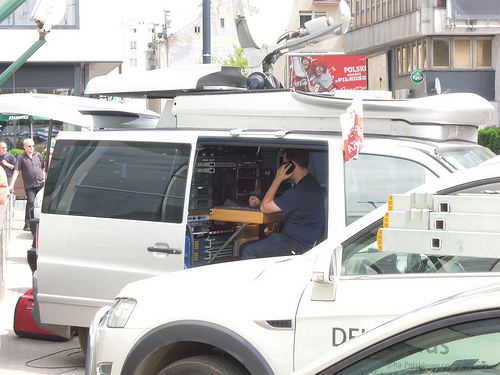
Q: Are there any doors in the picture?
A: Yes, there is a door.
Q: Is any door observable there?
A: Yes, there is a door.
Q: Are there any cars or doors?
A: Yes, there is a door.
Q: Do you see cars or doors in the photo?
A: Yes, there is a door.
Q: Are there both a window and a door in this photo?
A: Yes, there are both a door and a window.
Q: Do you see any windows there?
A: Yes, there is a window.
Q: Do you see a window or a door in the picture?
A: Yes, there is a window.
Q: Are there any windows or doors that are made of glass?
A: Yes, the window is made of glass.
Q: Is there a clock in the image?
A: No, there are no clocks.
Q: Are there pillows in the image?
A: No, there are no pillows.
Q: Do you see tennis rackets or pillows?
A: No, there are no pillows or tennis rackets.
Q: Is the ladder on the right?
A: Yes, the ladder is on the right of the image.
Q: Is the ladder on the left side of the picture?
A: No, the ladder is on the right of the image.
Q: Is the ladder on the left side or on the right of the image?
A: The ladder is on the right of the image.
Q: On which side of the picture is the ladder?
A: The ladder is on the right of the image.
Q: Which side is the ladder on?
A: The ladder is on the right of the image.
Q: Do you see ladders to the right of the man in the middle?
A: Yes, there is a ladder to the right of the man.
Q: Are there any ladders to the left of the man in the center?
A: No, the ladder is to the right of the man.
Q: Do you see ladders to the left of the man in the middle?
A: No, the ladder is to the right of the man.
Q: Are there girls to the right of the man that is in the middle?
A: No, there is a ladder to the right of the man.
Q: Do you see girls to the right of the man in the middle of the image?
A: No, there is a ladder to the right of the man.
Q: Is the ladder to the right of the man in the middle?
A: Yes, the ladder is to the right of the man.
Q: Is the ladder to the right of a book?
A: No, the ladder is to the right of the man.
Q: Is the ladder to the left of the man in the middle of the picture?
A: No, the ladder is to the right of the man.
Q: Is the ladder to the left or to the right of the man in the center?
A: The ladder is to the right of the man.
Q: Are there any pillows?
A: No, there are no pillows.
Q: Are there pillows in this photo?
A: No, there are no pillows.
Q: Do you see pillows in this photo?
A: No, there are no pillows.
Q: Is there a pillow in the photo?
A: No, there are no pillows.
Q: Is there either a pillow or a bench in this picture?
A: No, there are no pillows or benches.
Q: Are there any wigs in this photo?
A: No, there are no wigs.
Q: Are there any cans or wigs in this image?
A: No, there are no wigs or cans.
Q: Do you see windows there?
A: Yes, there is a window.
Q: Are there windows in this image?
A: Yes, there is a window.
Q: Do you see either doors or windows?
A: Yes, there is a window.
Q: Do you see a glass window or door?
A: Yes, there is a glass window.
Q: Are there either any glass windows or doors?
A: Yes, there is a glass window.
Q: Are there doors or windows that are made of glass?
A: Yes, the window is made of glass.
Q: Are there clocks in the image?
A: No, there are no clocks.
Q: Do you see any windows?
A: Yes, there is a window.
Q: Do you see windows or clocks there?
A: Yes, there is a window.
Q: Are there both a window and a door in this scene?
A: Yes, there are both a window and a door.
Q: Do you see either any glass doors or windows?
A: Yes, there is a glass window.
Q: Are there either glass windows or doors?
A: Yes, there is a glass window.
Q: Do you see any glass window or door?
A: Yes, there is a glass window.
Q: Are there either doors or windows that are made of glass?
A: Yes, the window is made of glass.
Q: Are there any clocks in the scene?
A: No, there are no clocks.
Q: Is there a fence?
A: No, there are no fences.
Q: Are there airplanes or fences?
A: No, there are no fences or airplanes.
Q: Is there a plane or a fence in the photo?
A: No, there are no fences or airplanes.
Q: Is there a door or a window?
A: Yes, there is a window.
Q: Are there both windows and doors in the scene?
A: Yes, there are both a window and a door.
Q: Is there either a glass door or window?
A: Yes, there is a glass window.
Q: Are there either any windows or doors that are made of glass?
A: Yes, the window is made of glass.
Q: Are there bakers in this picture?
A: No, there are no bakers.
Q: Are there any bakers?
A: No, there are no bakers.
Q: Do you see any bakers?
A: No, there are no bakers.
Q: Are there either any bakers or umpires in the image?
A: No, there are no bakers or umpires.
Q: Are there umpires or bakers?
A: No, there are no bakers or umpires.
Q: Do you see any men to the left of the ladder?
A: Yes, there is a man to the left of the ladder.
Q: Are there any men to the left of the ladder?
A: Yes, there is a man to the left of the ladder.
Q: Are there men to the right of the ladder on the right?
A: No, the man is to the left of the ladder.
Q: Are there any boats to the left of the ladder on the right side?
A: No, there is a man to the left of the ladder.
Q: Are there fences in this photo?
A: No, there are no fences.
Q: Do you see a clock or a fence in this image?
A: No, there are no fences or clocks.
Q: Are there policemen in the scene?
A: No, there are no policemen.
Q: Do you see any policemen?
A: No, there are no policemen.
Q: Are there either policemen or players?
A: No, there are no policemen or players.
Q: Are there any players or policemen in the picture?
A: No, there are no policemen or players.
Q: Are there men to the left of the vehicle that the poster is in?
A: Yes, there is a man to the left of the vehicle.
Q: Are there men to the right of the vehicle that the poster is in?
A: No, the man is to the left of the vehicle.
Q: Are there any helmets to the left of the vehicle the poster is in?
A: No, there is a man to the left of the vehicle.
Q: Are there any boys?
A: No, there are no boys.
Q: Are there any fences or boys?
A: No, there are no boys or fences.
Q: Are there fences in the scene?
A: No, there are no fences.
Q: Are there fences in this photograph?
A: No, there are no fences.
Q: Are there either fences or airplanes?
A: No, there are no fences or airplanes.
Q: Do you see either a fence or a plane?
A: No, there are no fences or airplanes.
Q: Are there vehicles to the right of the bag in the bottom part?
A: Yes, there is a vehicle to the right of the bag.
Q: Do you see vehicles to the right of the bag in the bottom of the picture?
A: Yes, there is a vehicle to the right of the bag.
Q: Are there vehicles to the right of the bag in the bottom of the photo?
A: Yes, there is a vehicle to the right of the bag.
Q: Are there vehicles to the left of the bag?
A: No, the vehicle is to the right of the bag.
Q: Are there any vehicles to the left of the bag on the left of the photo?
A: No, the vehicle is to the right of the bag.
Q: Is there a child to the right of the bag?
A: No, there is a vehicle to the right of the bag.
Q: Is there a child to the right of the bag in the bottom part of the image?
A: No, there is a vehicle to the right of the bag.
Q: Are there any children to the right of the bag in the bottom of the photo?
A: No, there is a vehicle to the right of the bag.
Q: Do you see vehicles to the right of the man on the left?
A: Yes, there is a vehicle to the right of the man.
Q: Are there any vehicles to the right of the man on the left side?
A: Yes, there is a vehicle to the right of the man.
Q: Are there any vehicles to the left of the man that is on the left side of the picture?
A: No, the vehicle is to the right of the man.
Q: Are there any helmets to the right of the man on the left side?
A: No, there is a vehicle to the right of the man.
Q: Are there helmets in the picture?
A: No, there are no helmets.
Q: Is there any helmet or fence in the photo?
A: No, there are no helmets or fences.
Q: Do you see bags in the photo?
A: Yes, there is a bag.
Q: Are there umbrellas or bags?
A: Yes, there is a bag.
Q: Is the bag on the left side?
A: Yes, the bag is on the left of the image.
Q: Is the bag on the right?
A: No, the bag is on the left of the image.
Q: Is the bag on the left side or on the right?
A: The bag is on the left of the image.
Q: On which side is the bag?
A: The bag is on the left of the image.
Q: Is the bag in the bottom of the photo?
A: Yes, the bag is in the bottom of the image.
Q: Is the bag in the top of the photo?
A: No, the bag is in the bottom of the image.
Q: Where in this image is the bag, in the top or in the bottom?
A: The bag is in the bottom of the image.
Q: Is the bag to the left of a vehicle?
A: Yes, the bag is to the left of a vehicle.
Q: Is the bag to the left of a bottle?
A: No, the bag is to the left of a vehicle.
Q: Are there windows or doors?
A: Yes, there is a window.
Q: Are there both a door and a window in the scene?
A: Yes, there are both a window and a door.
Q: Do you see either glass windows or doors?
A: Yes, there is a glass window.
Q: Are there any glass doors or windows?
A: Yes, there is a glass window.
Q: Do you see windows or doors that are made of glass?
A: Yes, the window is made of glass.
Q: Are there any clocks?
A: No, there are no clocks.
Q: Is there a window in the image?
A: Yes, there is a window.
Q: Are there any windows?
A: Yes, there is a window.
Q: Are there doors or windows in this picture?
A: Yes, there is a window.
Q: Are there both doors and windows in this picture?
A: Yes, there are both a window and a door.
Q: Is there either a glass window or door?
A: Yes, there is a glass window.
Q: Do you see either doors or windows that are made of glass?
A: Yes, the window is made of glass.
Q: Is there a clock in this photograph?
A: No, there are no clocks.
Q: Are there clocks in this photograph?
A: No, there are no clocks.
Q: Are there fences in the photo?
A: No, there are no fences.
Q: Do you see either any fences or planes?
A: No, there are no fences or planes.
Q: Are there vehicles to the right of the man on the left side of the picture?
A: Yes, there is a vehicle to the right of the man.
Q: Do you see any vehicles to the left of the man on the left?
A: No, the vehicle is to the right of the man.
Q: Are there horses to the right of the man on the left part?
A: No, there is a vehicle to the right of the man.